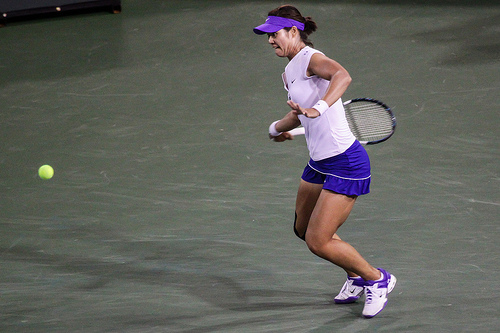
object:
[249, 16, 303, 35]
visor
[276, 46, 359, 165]
shirt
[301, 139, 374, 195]
skirt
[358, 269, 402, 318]
shoe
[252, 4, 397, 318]
woman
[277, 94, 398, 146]
racket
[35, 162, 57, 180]
ball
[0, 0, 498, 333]
ground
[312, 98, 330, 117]
sweatband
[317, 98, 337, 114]
wrist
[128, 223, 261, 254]
scuff mark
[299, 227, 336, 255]
knee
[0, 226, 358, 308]
shadow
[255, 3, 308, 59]
head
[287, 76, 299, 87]
nike logo